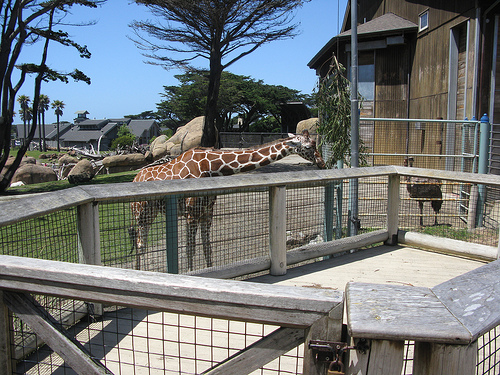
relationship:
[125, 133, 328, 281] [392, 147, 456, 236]
giraffe looking at bird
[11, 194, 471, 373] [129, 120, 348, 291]
pen in front of giraffe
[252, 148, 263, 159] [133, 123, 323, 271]
spot on giraffe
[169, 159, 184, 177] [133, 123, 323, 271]
spot on giraffe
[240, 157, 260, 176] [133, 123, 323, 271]
spot on giraffe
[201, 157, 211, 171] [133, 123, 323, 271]
spot on giraffe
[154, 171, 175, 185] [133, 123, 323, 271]
spot on giraffe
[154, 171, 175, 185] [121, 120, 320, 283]
spot on giraffe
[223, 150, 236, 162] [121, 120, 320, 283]
spot on giraffe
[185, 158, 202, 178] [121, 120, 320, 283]
spot on giraffe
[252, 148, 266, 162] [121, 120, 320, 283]
spot on giraffe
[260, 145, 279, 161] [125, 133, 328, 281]
spot on giraffe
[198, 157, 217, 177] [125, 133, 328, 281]
spot on giraffe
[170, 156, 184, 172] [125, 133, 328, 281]
spot on giraffe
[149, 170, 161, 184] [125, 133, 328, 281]
spot on giraffe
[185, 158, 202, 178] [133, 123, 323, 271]
spot on giraffe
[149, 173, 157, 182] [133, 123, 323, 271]
spot on giraffe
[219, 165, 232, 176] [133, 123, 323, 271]
spot on giraffe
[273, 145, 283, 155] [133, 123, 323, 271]
spot on giraffe